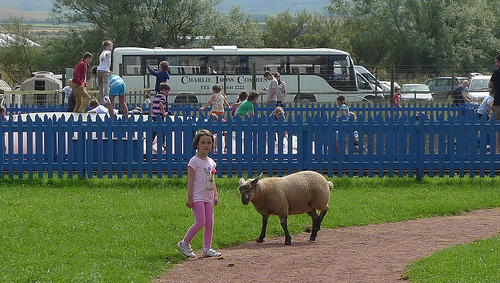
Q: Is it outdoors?
A: Yes, it is outdoors.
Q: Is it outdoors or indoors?
A: It is outdoors.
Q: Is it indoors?
A: No, it is outdoors.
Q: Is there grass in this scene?
A: Yes, there is grass.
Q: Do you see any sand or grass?
A: Yes, there is grass.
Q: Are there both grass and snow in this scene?
A: No, there is grass but no snow.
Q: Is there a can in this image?
A: No, there are no cans.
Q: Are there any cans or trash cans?
A: No, there are no cans or trash cans.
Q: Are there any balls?
A: No, there are no balls.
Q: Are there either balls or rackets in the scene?
A: No, there are no balls or rackets.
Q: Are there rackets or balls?
A: No, there are no balls or rackets.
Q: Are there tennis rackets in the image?
A: No, there are no tennis rackets.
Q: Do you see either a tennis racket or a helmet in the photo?
A: No, there are no rackets or helmets.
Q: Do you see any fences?
A: Yes, there is a fence.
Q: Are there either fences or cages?
A: Yes, there is a fence.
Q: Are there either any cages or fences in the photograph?
A: Yes, there is a fence.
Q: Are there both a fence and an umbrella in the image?
A: No, there is a fence but no umbrellas.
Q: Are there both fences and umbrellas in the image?
A: No, there is a fence but no umbrellas.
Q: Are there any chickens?
A: No, there are no chickens.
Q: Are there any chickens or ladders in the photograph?
A: No, there are no chickens or ladders.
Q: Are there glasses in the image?
A: No, there are no glasses.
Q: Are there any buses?
A: Yes, there is a bus.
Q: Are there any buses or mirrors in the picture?
A: Yes, there is a bus.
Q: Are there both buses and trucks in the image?
A: No, there is a bus but no trucks.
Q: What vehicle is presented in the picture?
A: The vehicle is a bus.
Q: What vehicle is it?
A: The vehicle is a bus.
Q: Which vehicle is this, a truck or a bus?
A: This is a bus.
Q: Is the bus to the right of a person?
A: Yes, the bus is to the right of a person.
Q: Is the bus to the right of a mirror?
A: No, the bus is to the right of a person.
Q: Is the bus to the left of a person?
A: No, the bus is to the right of a person.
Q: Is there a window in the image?
A: Yes, there is a window.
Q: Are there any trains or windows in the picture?
A: Yes, there is a window.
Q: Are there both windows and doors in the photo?
A: No, there is a window but no doors.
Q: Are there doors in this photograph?
A: No, there are no doors.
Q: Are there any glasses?
A: No, there are no glasses.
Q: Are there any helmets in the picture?
A: No, there are no helmets.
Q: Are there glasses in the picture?
A: No, there are no glasses.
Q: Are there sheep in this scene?
A: Yes, there is a sheep.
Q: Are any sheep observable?
A: Yes, there is a sheep.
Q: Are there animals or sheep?
A: Yes, there is a sheep.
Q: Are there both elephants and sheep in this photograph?
A: No, there is a sheep but no elephants.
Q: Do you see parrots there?
A: No, there are no parrots.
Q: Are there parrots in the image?
A: No, there are no parrots.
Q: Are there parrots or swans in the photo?
A: No, there are no parrots or swans.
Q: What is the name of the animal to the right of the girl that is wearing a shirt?
A: The animal is a sheep.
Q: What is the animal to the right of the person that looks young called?
A: The animal is a sheep.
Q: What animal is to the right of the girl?
A: The animal is a sheep.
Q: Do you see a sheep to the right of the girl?
A: Yes, there is a sheep to the right of the girl.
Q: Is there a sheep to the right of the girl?
A: Yes, there is a sheep to the right of the girl.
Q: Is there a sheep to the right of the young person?
A: Yes, there is a sheep to the right of the girl.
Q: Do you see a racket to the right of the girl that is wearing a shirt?
A: No, there is a sheep to the right of the girl.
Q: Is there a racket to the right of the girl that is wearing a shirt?
A: No, there is a sheep to the right of the girl.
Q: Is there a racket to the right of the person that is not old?
A: No, there is a sheep to the right of the girl.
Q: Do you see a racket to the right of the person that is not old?
A: No, there is a sheep to the right of the girl.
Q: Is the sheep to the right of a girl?
A: Yes, the sheep is to the right of a girl.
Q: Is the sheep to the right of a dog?
A: No, the sheep is to the right of a girl.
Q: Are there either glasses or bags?
A: No, there are no glasses or bags.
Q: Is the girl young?
A: Yes, the girl is young.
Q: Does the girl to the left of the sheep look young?
A: Yes, the girl is young.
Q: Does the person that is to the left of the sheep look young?
A: Yes, the girl is young.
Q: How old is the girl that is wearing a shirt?
A: The girl is young.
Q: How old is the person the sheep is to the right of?
A: The girl is young.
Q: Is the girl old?
A: No, the girl is young.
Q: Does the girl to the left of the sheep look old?
A: No, the girl is young.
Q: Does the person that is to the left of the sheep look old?
A: No, the girl is young.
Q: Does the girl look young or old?
A: The girl is young.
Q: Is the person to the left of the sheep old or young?
A: The girl is young.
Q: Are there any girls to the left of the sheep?
A: Yes, there is a girl to the left of the sheep.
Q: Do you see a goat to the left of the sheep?
A: No, there is a girl to the left of the sheep.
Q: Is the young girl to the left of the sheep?
A: Yes, the girl is to the left of the sheep.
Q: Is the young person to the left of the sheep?
A: Yes, the girl is to the left of the sheep.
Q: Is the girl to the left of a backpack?
A: No, the girl is to the left of the sheep.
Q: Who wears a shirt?
A: The girl wears a shirt.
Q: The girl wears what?
A: The girl wears a shirt.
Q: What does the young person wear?
A: The girl wears a shirt.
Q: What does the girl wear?
A: The girl wears a shirt.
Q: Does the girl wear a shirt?
A: Yes, the girl wears a shirt.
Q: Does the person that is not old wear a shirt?
A: Yes, the girl wears a shirt.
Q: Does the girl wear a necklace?
A: No, the girl wears a shirt.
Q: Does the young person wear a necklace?
A: No, the girl wears a shirt.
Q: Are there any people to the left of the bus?
A: Yes, there is a person to the left of the bus.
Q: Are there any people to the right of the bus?
A: No, the person is to the left of the bus.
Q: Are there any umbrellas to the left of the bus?
A: No, there is a person to the left of the bus.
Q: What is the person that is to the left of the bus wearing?
A: The person is wearing a shirt.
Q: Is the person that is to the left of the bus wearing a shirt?
A: Yes, the person is wearing a shirt.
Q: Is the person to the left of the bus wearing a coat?
A: No, the person is wearing a shirt.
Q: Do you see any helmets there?
A: No, there are no helmets.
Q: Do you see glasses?
A: No, there are no glasses.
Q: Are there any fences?
A: Yes, there is a fence.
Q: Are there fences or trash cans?
A: Yes, there is a fence.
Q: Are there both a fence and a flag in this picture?
A: No, there is a fence but no flags.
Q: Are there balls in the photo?
A: No, there are no balls.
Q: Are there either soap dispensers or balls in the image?
A: No, there are no balls or soap dispensers.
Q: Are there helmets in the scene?
A: No, there are no helmets.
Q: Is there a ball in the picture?
A: No, there are no balls.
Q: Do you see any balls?
A: No, there are no balls.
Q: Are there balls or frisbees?
A: No, there are no balls or frisbees.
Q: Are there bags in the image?
A: No, there are no bags.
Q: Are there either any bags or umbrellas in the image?
A: No, there are no bags or umbrellas.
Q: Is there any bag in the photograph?
A: No, there are no bags.